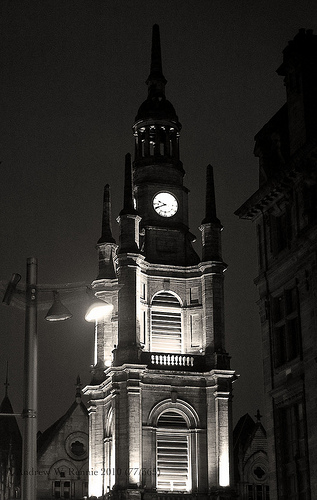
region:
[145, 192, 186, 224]
clock on the tower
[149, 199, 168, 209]
hands on the clock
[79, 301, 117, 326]
light on the pole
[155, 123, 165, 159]
column on the tower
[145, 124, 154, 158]
column on the tower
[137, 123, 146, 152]
column on the tower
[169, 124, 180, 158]
column on the tower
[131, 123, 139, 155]
column on the tower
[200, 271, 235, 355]
column on the tower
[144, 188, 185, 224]
a clock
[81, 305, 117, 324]
a street light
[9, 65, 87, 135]
the sky is dark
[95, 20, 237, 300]
a building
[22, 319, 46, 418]
a pole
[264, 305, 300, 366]
window on the building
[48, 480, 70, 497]
a window on the building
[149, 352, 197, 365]
a railing on the building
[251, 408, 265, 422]
a cross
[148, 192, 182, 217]
the light on the clock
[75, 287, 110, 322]
light hanging from line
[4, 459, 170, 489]
lettering and info on image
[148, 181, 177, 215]
clock on the building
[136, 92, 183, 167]
dome structure with columns on top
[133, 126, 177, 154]
columns encircling a structure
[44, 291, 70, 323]
light strung from line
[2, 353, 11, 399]
cross on top of building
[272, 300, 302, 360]
window on side of building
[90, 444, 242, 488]
light shining on the building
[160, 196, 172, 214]
A clock on the tower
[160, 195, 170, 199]
Light shining from the clock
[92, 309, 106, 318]
A bright lamp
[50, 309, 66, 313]
The fixture holding a lamp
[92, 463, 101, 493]
Lamp shining on the wall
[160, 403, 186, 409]
Arch on the door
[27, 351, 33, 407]
The pole holding the lamp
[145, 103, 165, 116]
Dome shaped roof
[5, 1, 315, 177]
SKY IS DARK AND STARLESS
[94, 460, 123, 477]
PHOTO WAS TAKEN IN 2010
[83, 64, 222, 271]
TALL TOWER AT NIGHT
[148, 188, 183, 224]
CLOCK ON FACE OF TOWER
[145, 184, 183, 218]
CLOCK IS LIT UP FOR NIGHTTIME VIEWING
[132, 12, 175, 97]
TOWER HAS LARGE SPIRE ON TOP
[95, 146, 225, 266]
THREE SPIRES ARE SEEN AROUND CLOCK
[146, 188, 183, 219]
CLOCK IS ROUND IN SHAPE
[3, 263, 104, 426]
STREET LIGHTS AT TOP OF POLE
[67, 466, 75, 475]
black print style letter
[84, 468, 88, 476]
black print style letter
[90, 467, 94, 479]
black print style letter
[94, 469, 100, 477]
black print style letter